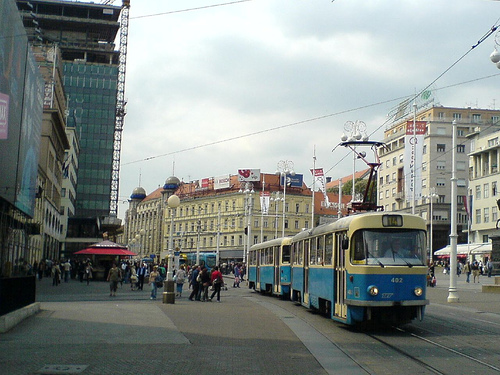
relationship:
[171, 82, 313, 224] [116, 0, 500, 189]
clouds in skies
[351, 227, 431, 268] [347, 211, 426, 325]
windshield on front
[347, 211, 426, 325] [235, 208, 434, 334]
front of bus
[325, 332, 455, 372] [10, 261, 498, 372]
tracks on ground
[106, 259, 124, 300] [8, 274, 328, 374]
person walking down street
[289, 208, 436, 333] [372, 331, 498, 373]
trolley car on tracks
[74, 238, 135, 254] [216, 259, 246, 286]
red canopy behind people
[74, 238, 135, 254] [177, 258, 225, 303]
red canopy behind people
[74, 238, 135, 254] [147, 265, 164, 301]
red canopy behind woman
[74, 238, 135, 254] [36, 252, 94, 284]
red canopy behind people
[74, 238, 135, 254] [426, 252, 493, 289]
red canopy behind people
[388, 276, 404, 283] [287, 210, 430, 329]
white numbers on front car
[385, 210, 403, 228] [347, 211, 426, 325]
fourteen on front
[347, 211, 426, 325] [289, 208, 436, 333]
front of trolley car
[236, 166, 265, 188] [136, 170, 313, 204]
sign on roof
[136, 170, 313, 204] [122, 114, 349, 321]
roof of building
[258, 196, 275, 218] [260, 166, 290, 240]
sign hanging on pole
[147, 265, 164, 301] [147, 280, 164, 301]
woman wearing blue jeans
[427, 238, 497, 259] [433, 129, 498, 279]
awning on building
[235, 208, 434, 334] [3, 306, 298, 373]
bus parked near sidewalk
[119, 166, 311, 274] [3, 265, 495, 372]
building near street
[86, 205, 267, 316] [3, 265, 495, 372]
people on street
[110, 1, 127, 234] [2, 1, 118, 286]
scaffolding along side of building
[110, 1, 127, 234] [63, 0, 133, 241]
scaffolding against building